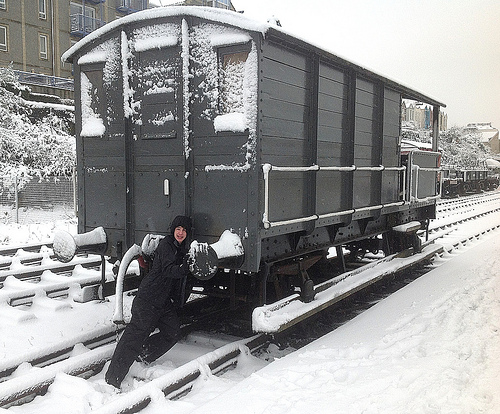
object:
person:
[81, 213, 194, 395]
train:
[47, 0, 451, 344]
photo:
[4, 2, 497, 413]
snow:
[21, 374, 97, 413]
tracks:
[82, 331, 268, 414]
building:
[1, 0, 242, 105]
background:
[1, 84, 78, 106]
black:
[153, 284, 158, 289]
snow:
[167, 5, 275, 34]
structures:
[405, 102, 414, 123]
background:
[403, 148, 499, 157]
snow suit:
[102, 234, 196, 390]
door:
[130, 34, 190, 233]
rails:
[268, 162, 320, 176]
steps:
[392, 220, 422, 234]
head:
[169, 215, 193, 245]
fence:
[0, 172, 77, 225]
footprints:
[378, 300, 498, 406]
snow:
[0, 178, 500, 414]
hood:
[170, 214, 193, 238]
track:
[0, 256, 104, 284]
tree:
[2, 58, 75, 224]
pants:
[104, 295, 183, 390]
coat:
[136, 234, 190, 315]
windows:
[37, 33, 49, 63]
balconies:
[67, 1, 105, 37]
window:
[215, 39, 257, 116]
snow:
[79, 13, 97, 20]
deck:
[380, 88, 404, 205]